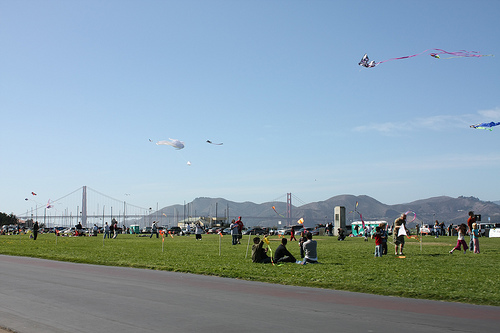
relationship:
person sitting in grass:
[270, 236, 297, 265] [1, 227, 498, 305]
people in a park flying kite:
[73, 209, 482, 264] [358, 48, 485, 65]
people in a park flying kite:
[73, 209, 482, 264] [151, 138, 223, 150]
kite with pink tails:
[353, 44, 484, 75] [377, 43, 497, 70]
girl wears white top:
[449, 223, 471, 251] [457, 231, 464, 238]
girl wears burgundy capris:
[449, 223, 471, 251] [453, 240, 466, 249]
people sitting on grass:
[0, 209, 500, 265] [0, 220, 500, 303]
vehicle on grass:
[273, 224, 310, 235] [1, 227, 498, 305]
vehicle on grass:
[61, 226, 87, 236] [1, 227, 498, 305]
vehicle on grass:
[417, 223, 432, 235] [1, 227, 498, 305]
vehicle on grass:
[169, 227, 179, 236] [1, 227, 498, 305]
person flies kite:
[193, 215, 204, 242] [352, 45, 379, 70]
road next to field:
[0, 250, 500, 333] [350, 264, 412, 288]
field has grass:
[350, 264, 412, 288] [398, 267, 440, 287]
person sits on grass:
[273, 237, 296, 264] [345, 253, 470, 317]